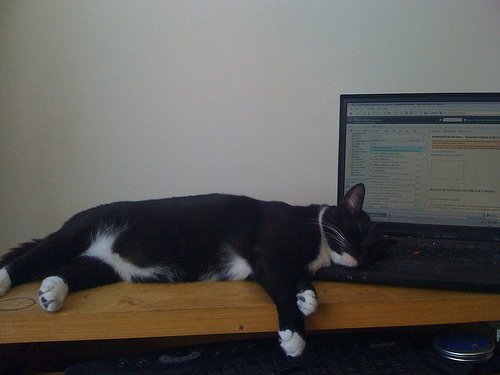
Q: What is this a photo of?
A: A sleeping cat.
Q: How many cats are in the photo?
A: One.